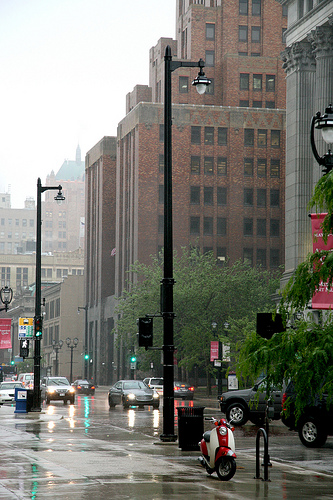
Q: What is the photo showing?
A: It is showing a street.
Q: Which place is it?
A: It is a street.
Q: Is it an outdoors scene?
A: Yes, it is outdoors.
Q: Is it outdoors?
A: Yes, it is outdoors.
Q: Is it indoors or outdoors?
A: It is outdoors.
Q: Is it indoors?
A: No, it is outdoors.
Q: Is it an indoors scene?
A: No, it is outdoors.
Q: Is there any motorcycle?
A: Yes, there is a motorcycle.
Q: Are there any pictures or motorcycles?
A: Yes, there is a motorcycle.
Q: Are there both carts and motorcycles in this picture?
A: No, there is a motorcycle but no carts.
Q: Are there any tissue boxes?
A: No, there are no tissue boxes.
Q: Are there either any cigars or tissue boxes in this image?
A: No, there are no tissue boxes or cigars.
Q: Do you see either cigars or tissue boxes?
A: No, there are no tissue boxes or cigars.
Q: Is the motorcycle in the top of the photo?
A: No, the motorcycle is in the bottom of the image.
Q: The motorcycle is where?
A: The motorcycle is on the sidewalk.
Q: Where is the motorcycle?
A: The motorcycle is on the sidewalk.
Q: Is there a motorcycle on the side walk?
A: Yes, there is a motorcycle on the side walk.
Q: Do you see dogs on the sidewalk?
A: No, there is a motorcycle on the sidewalk.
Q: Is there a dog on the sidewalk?
A: No, there is a motorcycle on the sidewalk.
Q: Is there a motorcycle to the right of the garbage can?
A: Yes, there is a motorcycle to the right of the garbage can.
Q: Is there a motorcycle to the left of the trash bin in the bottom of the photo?
A: No, the motorcycle is to the right of the garbage can.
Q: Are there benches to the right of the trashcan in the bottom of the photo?
A: No, there is a motorcycle to the right of the garbage bin.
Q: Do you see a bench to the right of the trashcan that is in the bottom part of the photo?
A: No, there is a motorcycle to the right of the garbage bin.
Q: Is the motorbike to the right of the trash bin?
A: Yes, the motorbike is to the right of the trash bin.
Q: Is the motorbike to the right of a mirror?
A: No, the motorbike is to the right of the trash bin.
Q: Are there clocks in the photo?
A: No, there are no clocks.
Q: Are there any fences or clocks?
A: No, there are no clocks or fences.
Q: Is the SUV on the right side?
A: Yes, the SUV is on the right of the image.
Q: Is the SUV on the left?
A: No, the SUV is on the right of the image.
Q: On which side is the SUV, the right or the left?
A: The SUV is on the right of the image.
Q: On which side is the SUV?
A: The SUV is on the right of the image.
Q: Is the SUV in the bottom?
A: Yes, the SUV is in the bottom of the image.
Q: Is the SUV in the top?
A: No, the SUV is in the bottom of the image.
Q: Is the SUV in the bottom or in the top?
A: The SUV is in the bottom of the image.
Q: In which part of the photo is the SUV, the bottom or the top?
A: The SUV is in the bottom of the image.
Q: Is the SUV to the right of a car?
A: Yes, the SUV is to the right of a car.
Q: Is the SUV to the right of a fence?
A: No, the SUV is to the right of a car.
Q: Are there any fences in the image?
A: No, there are no fences.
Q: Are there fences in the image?
A: No, there are no fences.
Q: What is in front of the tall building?
A: The trees are in front of the building.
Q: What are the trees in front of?
A: The trees are in front of the building.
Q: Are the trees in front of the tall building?
A: Yes, the trees are in front of the building.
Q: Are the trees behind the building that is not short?
A: No, the trees are in front of the building.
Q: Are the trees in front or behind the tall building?
A: The trees are in front of the building.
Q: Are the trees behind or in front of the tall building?
A: The trees are in front of the building.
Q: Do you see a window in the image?
A: Yes, there are windows.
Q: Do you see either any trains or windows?
A: Yes, there are windows.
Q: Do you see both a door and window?
A: No, there are windows but no doors.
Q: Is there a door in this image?
A: No, there are no doors.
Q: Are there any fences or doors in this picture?
A: No, there are no doors or fences.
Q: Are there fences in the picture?
A: No, there are no fences.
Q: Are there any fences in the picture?
A: No, there are no fences.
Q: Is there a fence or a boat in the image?
A: No, there are no fences or boats.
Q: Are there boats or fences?
A: No, there are no fences or boats.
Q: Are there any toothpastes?
A: No, there are no toothpastes.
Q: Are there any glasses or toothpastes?
A: No, there are no toothpastes or glasses.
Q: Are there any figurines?
A: No, there are no figurines.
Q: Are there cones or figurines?
A: No, there are no figurines or cones.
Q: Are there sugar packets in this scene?
A: No, there are no sugar packets.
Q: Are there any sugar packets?
A: No, there are no sugar packets.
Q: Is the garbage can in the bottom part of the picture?
A: Yes, the garbage can is in the bottom of the image.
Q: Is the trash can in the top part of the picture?
A: No, the trash can is in the bottom of the image.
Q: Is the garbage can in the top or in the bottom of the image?
A: The garbage can is in the bottom of the image.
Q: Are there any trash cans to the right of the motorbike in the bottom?
A: No, the trash can is to the left of the motorbike.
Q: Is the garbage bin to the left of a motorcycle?
A: Yes, the garbage bin is to the left of a motorcycle.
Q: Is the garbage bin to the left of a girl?
A: No, the garbage bin is to the left of a motorcycle.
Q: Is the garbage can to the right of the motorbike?
A: No, the garbage can is to the left of the motorbike.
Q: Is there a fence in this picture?
A: No, there are no fences.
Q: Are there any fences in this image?
A: No, there are no fences.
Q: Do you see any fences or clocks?
A: No, there are no fences or clocks.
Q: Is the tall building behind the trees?
A: Yes, the building is behind the trees.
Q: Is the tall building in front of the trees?
A: No, the building is behind the trees.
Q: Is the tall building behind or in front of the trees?
A: The building is behind the trees.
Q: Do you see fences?
A: No, there are no fences.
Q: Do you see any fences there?
A: No, there are no fences.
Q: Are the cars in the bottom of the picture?
A: Yes, the cars are in the bottom of the image.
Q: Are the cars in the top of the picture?
A: No, the cars are in the bottom of the image.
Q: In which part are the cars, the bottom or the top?
A: The cars are in the bottom of the image.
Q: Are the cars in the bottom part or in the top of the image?
A: The cars are in the bottom of the image.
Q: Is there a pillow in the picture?
A: No, there are no pillows.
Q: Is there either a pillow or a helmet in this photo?
A: No, there are no pillows or helmets.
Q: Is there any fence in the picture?
A: No, there are no fences.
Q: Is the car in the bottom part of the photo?
A: Yes, the car is in the bottom of the image.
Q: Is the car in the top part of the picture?
A: No, the car is in the bottom of the image.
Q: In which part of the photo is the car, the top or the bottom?
A: The car is in the bottom of the image.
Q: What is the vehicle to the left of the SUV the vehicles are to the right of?
A: The vehicle is a car.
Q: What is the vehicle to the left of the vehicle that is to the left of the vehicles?
A: The vehicle is a car.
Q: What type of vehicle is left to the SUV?
A: The vehicle is a car.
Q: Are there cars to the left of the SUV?
A: Yes, there is a car to the left of the SUV.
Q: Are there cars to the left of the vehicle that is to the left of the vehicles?
A: Yes, there is a car to the left of the SUV.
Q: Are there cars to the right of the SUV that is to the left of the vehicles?
A: No, the car is to the left of the SUV.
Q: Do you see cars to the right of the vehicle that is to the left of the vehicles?
A: No, the car is to the left of the SUV.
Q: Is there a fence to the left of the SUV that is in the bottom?
A: No, there is a car to the left of the SUV.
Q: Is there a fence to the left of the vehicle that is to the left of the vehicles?
A: No, there is a car to the left of the SUV.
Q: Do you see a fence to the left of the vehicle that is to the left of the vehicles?
A: No, there is a car to the left of the SUV.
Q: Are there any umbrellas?
A: No, there are no umbrellas.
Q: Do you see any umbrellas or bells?
A: No, there are no umbrellas or bells.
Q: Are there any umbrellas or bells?
A: No, there are no umbrellas or bells.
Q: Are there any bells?
A: No, there are no bells.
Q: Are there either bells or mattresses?
A: No, there are no bells or mattresses.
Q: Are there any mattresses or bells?
A: No, there are no bells or mattresses.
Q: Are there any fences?
A: No, there are no fences.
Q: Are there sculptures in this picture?
A: No, there are no sculptures.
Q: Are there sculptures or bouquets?
A: No, there are no sculptures or bouquets.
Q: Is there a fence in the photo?
A: No, there are no fences.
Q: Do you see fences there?
A: No, there are no fences.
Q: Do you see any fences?
A: No, there are no fences.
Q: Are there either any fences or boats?
A: No, there are no fences or boats.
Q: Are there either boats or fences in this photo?
A: No, there are no fences or boats.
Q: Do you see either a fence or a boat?
A: No, there are no fences or boats.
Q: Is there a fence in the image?
A: No, there are no fences.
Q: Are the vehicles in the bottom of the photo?
A: Yes, the vehicles are in the bottom of the image.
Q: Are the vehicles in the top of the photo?
A: No, the vehicles are in the bottom of the image.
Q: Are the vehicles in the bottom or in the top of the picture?
A: The vehicles are in the bottom of the image.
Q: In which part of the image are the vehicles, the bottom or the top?
A: The vehicles are in the bottom of the image.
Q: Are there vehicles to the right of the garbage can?
A: Yes, there are vehicles to the right of the garbage can.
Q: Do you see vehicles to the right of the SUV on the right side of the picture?
A: Yes, there are vehicles to the right of the SUV.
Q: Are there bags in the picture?
A: No, there are no bags.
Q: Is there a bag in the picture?
A: No, there are no bags.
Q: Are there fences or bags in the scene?
A: No, there are no bags or fences.